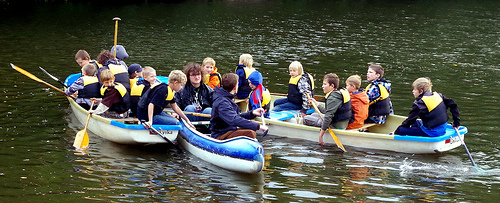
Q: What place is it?
A: It is a river.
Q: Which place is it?
A: It is a river.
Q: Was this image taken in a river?
A: Yes, it was taken in a river.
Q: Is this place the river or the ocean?
A: It is the river.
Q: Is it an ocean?
A: No, it is a river.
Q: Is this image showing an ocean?
A: No, the picture is showing a river.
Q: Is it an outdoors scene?
A: Yes, it is outdoors.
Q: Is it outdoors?
A: Yes, it is outdoors.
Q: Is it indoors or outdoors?
A: It is outdoors.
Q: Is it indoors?
A: No, it is outdoors.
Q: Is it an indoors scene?
A: No, it is outdoors.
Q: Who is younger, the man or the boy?
A: The boy is younger than the man.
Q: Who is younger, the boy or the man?
A: The boy is younger than the man.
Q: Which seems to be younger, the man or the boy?
A: The boy is younger than the man.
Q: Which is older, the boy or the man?
A: The man is older than the boy.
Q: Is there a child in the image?
A: Yes, there is a child.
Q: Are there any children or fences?
A: Yes, there is a child.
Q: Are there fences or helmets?
A: No, there are no fences or helmets.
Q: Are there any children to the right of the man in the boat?
A: Yes, there is a child to the right of the man.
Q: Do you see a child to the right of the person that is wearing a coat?
A: Yes, there is a child to the right of the man.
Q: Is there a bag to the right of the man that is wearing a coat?
A: No, there is a child to the right of the man.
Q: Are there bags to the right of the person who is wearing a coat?
A: No, there is a child to the right of the man.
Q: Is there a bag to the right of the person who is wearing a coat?
A: No, there is a child to the right of the man.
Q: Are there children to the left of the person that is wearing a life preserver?
A: Yes, there is a child to the left of the boy.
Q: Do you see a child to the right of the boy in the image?
A: No, the child is to the left of the boy.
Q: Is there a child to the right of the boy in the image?
A: No, the child is to the left of the boy.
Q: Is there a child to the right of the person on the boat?
A: No, the child is to the left of the boy.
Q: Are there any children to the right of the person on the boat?
A: No, the child is to the left of the boy.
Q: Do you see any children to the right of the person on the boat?
A: No, the child is to the left of the boy.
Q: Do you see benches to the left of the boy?
A: No, there is a child to the left of the boy.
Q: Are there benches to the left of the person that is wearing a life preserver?
A: No, there is a child to the left of the boy.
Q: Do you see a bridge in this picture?
A: No, there are no bridges.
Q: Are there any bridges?
A: No, there are no bridges.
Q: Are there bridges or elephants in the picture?
A: No, there are no bridges or elephants.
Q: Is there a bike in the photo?
A: No, there are no bikes.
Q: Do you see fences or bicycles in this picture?
A: No, there are no bicycles or fences.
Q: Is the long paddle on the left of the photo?
A: Yes, the oar is on the left of the image.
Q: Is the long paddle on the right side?
A: No, the oar is on the left of the image.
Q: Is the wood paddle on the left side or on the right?
A: The paddle is on the left of the image.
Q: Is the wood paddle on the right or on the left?
A: The paddle is on the left of the image.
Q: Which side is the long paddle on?
A: The paddle is on the left of the image.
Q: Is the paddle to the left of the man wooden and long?
A: Yes, the oar is wooden and long.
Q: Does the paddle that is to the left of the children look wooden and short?
A: No, the oar is wooden but long.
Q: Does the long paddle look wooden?
A: Yes, the paddle is wooden.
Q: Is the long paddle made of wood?
A: Yes, the oar is made of wood.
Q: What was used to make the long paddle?
A: The paddle is made of wood.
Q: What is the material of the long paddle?
A: The paddle is made of wood.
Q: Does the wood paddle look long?
A: Yes, the paddle is long.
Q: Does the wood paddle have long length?
A: Yes, the paddle is long.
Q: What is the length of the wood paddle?
A: The paddle is long.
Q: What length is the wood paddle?
A: The paddle is long.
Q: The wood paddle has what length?
A: The paddle is long.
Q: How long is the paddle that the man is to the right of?
A: The paddle is long.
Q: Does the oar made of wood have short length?
A: No, the paddle is long.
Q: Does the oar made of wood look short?
A: No, the paddle is long.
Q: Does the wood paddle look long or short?
A: The paddle is long.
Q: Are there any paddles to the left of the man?
A: Yes, there is a paddle to the left of the man.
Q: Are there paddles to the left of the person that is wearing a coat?
A: Yes, there is a paddle to the left of the man.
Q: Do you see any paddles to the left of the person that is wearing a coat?
A: Yes, there is a paddle to the left of the man.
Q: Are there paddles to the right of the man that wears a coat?
A: No, the paddle is to the left of the man.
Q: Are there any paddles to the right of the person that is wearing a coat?
A: No, the paddle is to the left of the man.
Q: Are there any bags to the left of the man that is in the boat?
A: No, there is a paddle to the left of the man.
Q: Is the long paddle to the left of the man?
A: Yes, the paddle is to the left of the man.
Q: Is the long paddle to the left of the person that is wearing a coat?
A: Yes, the paddle is to the left of the man.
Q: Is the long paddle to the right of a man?
A: No, the paddle is to the left of a man.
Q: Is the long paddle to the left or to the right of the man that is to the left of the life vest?
A: The paddle is to the left of the man.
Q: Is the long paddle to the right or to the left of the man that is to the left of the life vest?
A: The paddle is to the left of the man.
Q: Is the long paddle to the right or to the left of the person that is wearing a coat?
A: The paddle is to the left of the man.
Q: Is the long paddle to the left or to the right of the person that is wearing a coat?
A: The paddle is to the left of the man.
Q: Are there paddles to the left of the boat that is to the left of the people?
A: Yes, there is a paddle to the left of the boat.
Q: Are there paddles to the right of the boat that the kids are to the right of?
A: No, the paddle is to the left of the boat.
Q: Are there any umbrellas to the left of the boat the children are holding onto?
A: No, there is a paddle to the left of the boat.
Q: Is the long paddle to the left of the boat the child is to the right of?
A: Yes, the paddle is to the left of the boat.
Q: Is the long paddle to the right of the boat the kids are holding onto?
A: No, the oar is to the left of the boat.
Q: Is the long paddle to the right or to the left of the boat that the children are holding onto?
A: The oar is to the left of the boat.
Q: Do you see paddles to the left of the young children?
A: Yes, there is a paddle to the left of the children.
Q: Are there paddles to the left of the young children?
A: Yes, there is a paddle to the left of the children.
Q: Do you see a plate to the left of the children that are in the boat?
A: No, there is a paddle to the left of the kids.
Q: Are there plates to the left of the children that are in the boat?
A: No, there is a paddle to the left of the kids.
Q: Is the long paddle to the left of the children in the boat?
A: Yes, the oar is to the left of the kids.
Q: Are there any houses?
A: No, there are no houses.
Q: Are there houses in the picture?
A: No, there are no houses.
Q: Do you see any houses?
A: No, there are no houses.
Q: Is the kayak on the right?
A: No, the kayak is on the left of the image.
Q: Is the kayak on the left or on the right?
A: The kayak is on the left of the image.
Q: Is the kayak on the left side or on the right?
A: The kayak is on the left of the image.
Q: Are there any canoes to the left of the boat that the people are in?
A: Yes, there is a canoe to the left of the boat.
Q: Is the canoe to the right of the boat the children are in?
A: No, the canoe is to the left of the boat.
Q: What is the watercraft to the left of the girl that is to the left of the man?
A: The watercraft is a canoe.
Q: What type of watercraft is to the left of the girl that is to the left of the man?
A: The watercraft is a canoe.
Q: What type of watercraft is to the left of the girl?
A: The watercraft is a canoe.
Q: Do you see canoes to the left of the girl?
A: Yes, there is a canoe to the left of the girl.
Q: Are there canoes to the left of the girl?
A: Yes, there is a canoe to the left of the girl.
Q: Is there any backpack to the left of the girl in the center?
A: No, there is a canoe to the left of the girl.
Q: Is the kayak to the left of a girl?
A: Yes, the kayak is to the left of a girl.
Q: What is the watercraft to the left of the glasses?
A: The watercraft is a canoe.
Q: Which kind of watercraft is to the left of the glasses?
A: The watercraft is a canoe.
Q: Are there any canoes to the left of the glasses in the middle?
A: Yes, there is a canoe to the left of the glasses.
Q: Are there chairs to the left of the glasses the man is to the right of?
A: No, there is a canoe to the left of the glasses.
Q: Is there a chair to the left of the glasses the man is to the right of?
A: No, there is a canoe to the left of the glasses.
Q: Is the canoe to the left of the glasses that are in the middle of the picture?
A: Yes, the canoe is to the left of the glasses.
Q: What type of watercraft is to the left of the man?
A: The watercraft is a canoe.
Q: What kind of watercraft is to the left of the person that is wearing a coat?
A: The watercraft is a canoe.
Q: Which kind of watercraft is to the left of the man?
A: The watercraft is a canoe.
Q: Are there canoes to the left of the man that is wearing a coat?
A: Yes, there is a canoe to the left of the man.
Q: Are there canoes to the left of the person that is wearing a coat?
A: Yes, there is a canoe to the left of the man.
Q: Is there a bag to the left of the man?
A: No, there is a canoe to the left of the man.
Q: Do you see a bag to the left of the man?
A: No, there is a canoe to the left of the man.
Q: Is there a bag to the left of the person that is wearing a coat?
A: No, there is a canoe to the left of the man.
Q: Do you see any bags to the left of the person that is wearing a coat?
A: No, there is a canoe to the left of the man.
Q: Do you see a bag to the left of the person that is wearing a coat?
A: No, there is a canoe to the left of the man.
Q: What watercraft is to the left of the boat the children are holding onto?
A: The watercraft is a canoe.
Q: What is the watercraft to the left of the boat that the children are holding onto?
A: The watercraft is a canoe.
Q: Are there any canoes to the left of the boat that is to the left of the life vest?
A: Yes, there is a canoe to the left of the boat.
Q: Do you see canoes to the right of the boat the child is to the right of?
A: No, the canoe is to the left of the boat.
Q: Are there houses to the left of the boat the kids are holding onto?
A: No, there is a canoe to the left of the boat.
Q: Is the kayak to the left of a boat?
A: Yes, the kayak is to the left of a boat.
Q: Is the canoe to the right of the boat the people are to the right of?
A: No, the canoe is to the left of the boat.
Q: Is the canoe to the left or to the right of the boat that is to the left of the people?
A: The canoe is to the left of the boat.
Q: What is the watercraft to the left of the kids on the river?
A: The watercraft is a canoe.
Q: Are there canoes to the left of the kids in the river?
A: Yes, there is a canoe to the left of the children.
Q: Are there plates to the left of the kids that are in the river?
A: No, there is a canoe to the left of the children.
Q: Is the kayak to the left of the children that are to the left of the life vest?
A: Yes, the kayak is to the left of the kids.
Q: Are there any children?
A: Yes, there are children.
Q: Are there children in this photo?
A: Yes, there are children.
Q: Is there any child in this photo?
A: Yes, there are children.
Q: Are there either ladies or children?
A: Yes, there are children.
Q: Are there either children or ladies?
A: Yes, there are children.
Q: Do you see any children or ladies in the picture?
A: Yes, there are children.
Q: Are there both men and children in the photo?
A: Yes, there are both children and a man.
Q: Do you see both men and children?
A: Yes, there are both children and a man.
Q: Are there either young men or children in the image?
A: Yes, there are young children.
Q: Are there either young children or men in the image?
A: Yes, there are young children.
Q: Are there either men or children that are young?
A: Yes, the children are young.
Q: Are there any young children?
A: Yes, there are young children.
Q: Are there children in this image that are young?
A: Yes, there are children that are young.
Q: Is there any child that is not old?
A: Yes, there are young children.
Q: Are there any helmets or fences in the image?
A: No, there are no helmets or fences.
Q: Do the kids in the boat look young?
A: Yes, the kids are young.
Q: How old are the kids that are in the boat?
A: The kids are young.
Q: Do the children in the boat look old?
A: No, the kids are young.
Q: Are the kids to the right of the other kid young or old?
A: The children are young.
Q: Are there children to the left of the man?
A: Yes, there are children to the left of the man.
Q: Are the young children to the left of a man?
A: Yes, the kids are to the left of a man.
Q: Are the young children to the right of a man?
A: No, the children are to the left of a man.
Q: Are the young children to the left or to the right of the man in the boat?
A: The children are to the left of the man.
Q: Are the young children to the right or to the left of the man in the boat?
A: The children are to the left of the man.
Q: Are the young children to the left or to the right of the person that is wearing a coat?
A: The children are to the left of the man.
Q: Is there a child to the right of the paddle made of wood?
A: Yes, there are children to the right of the oar.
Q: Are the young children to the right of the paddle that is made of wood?
A: Yes, the children are to the right of the paddle.